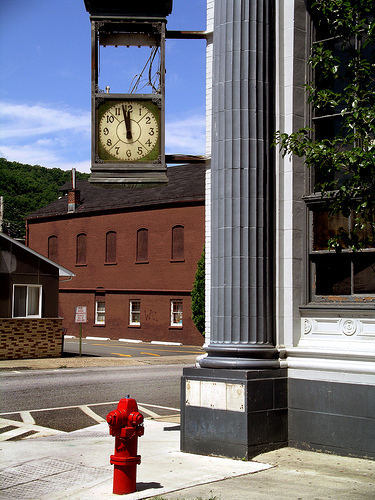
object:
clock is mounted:
[86, 16, 223, 185]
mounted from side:
[153, 25, 216, 166]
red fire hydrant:
[102, 389, 148, 500]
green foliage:
[265, 0, 374, 259]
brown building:
[17, 209, 207, 348]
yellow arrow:
[140, 350, 162, 358]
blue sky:
[2, 2, 205, 161]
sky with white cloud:
[0, 105, 214, 171]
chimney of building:
[64, 185, 80, 216]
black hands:
[125, 110, 133, 140]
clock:
[91, 93, 167, 167]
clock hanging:
[86, 7, 170, 188]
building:
[196, 3, 375, 456]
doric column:
[209, 0, 281, 373]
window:
[301, 0, 375, 318]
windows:
[132, 223, 152, 267]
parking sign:
[73, 304, 88, 358]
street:
[0, 357, 175, 411]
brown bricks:
[1, 318, 64, 357]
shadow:
[138, 477, 164, 493]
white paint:
[0, 393, 184, 442]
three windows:
[92, 292, 185, 331]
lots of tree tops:
[21, 173, 39, 193]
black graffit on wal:
[144, 307, 161, 324]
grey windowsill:
[306, 292, 375, 319]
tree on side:
[190, 244, 209, 342]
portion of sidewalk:
[0, 444, 371, 500]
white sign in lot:
[74, 304, 89, 323]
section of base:
[180, 374, 249, 415]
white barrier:
[0, 415, 275, 500]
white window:
[11, 283, 44, 321]